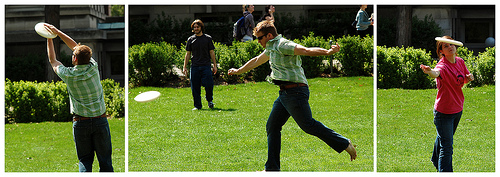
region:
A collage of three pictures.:
[16, 0, 486, 169]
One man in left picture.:
[13, 8, 115, 160]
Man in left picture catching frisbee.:
[13, 11, 118, 163]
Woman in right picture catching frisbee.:
[380, 14, 486, 166]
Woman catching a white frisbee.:
[408, 14, 480, 171]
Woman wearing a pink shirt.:
[420, 25, 482, 127]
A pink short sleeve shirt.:
[421, 46, 476, 117]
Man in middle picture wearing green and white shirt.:
[236, 17, 349, 163]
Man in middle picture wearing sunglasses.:
[246, 15, 308, 78]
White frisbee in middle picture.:
[132, 72, 174, 125]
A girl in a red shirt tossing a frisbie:
[420, 21, 465, 117]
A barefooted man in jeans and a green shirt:
[237, 13, 364, 170]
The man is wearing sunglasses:
[244, 20, 281, 48]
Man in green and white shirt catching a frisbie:
[36, 4, 106, 124]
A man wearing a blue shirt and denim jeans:
[173, 11, 233, 116]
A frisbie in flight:
[128, 77, 172, 126]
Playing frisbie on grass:
[143, 18, 361, 159]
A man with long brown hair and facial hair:
[188, 15, 206, 40]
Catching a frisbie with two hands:
[36, 17, 68, 54]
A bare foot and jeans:
[263, 92, 360, 161]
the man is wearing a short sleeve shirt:
[57, 60, 109, 118]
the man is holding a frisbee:
[38, 21, 113, 163]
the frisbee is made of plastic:
[33, 20, 60, 41]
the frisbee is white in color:
[35, 22, 58, 39]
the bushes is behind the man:
[4, 75, 126, 120]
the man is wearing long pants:
[262, 83, 351, 170]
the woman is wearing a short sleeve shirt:
[433, 55, 468, 110]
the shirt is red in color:
[433, 57, 470, 111]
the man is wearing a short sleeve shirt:
[184, 33, 214, 64]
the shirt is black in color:
[186, 33, 216, 65]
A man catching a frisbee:
[27, 18, 117, 173]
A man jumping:
[222, 11, 363, 168]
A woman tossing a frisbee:
[411, 19, 480, 166]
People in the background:
[233, 10, 373, 43]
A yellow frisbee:
[131, 78, 166, 113]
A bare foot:
[324, 125, 366, 167]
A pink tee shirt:
[429, 51, 470, 120]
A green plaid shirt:
[68, 60, 108, 125]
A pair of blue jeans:
[262, 76, 350, 163]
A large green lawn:
[169, 95, 245, 165]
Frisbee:
[25, 12, 116, 168]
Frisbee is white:
[30, 15, 60, 45]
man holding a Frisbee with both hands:
[30, 16, 123, 171]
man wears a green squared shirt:
[35, 18, 120, 173]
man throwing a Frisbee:
[122, 16, 368, 121]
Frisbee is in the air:
[130, 75, 170, 110]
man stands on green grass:
[175, 15, 225, 115]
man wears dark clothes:
[175, 10, 222, 110]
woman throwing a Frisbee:
[413, 28, 480, 168]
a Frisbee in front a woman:
[423, 28, 473, 53]